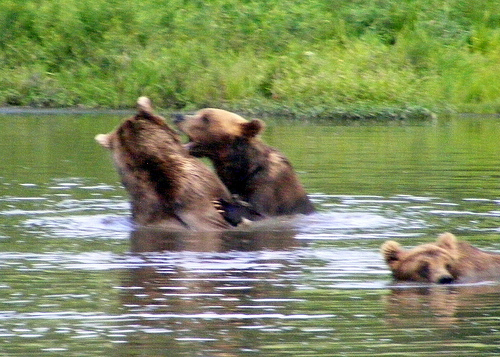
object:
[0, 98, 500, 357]
water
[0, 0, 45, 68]
trees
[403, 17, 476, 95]
bushes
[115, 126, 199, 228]
fur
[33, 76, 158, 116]
bank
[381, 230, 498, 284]
bear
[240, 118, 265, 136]
ear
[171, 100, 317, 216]
bear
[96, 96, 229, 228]
bear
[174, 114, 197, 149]
bear's mouth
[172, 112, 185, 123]
nose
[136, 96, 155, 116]
ear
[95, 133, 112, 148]
ear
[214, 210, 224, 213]
claws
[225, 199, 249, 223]
paw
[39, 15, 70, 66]
bush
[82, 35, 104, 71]
bush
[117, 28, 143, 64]
bush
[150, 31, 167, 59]
bush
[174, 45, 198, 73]
bush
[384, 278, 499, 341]
reflectio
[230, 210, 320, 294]
reflectio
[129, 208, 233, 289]
reflectio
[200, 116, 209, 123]
ee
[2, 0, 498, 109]
vegetatio